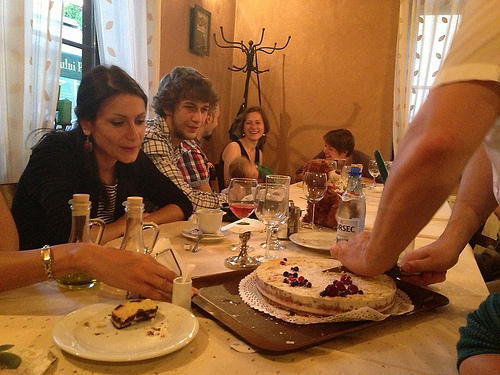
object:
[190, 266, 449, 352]
tray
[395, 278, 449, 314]
tray part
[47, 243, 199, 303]
hand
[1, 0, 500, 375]
family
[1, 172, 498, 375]
dinner table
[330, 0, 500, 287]
person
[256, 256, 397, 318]
pie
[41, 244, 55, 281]
watch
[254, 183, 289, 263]
wine glass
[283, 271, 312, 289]
fruit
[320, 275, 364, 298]
fruit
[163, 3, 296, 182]
corner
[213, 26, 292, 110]
coat rack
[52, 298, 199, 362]
plate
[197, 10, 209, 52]
picture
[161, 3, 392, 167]
wall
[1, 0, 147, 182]
window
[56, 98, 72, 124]
candle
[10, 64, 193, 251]
woman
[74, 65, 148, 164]
head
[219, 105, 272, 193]
woman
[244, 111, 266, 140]
head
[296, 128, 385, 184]
woman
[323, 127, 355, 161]
head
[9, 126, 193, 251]
shirt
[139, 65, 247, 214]
man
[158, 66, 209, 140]
head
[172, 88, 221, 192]
man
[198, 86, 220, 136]
head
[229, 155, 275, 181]
baby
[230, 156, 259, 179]
head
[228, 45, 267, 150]
purse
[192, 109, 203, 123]
nose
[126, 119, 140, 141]
nose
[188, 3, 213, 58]
frame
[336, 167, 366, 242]
bottled water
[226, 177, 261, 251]
wine glass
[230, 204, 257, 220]
wine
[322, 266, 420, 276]
knife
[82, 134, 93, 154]
earring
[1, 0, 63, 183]
curtain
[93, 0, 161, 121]
curtain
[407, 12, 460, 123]
window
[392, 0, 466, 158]
curtain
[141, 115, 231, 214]
shirt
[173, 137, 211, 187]
shirt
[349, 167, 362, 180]
bottle cap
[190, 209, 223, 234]
cup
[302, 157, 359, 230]
toy